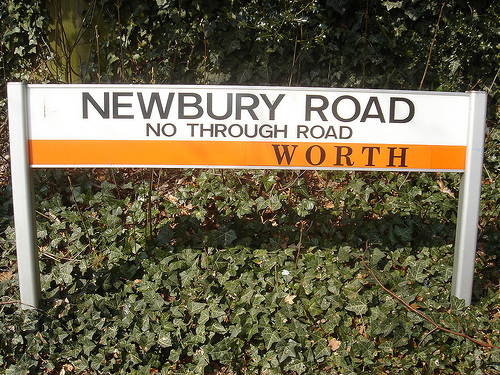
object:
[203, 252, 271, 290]
clovers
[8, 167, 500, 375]
ivy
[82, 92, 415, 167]
text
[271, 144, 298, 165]
letter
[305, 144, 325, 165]
letter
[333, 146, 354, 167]
letter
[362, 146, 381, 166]
letter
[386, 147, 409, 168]
letter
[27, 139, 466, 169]
orange area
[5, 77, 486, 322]
microphone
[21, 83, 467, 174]
sign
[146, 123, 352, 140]
letters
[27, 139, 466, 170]
backdrop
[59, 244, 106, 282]
leaves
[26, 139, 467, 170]
stripe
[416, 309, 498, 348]
twigs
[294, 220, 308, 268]
twigs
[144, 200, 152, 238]
twigs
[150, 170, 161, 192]
twigs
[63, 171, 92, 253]
twigs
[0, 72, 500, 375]
ground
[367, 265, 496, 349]
branch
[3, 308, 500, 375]
plant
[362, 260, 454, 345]
twigs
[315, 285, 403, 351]
greenery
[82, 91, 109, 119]
letters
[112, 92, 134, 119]
letters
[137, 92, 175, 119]
letters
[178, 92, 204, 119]
letters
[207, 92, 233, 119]
letters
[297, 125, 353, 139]
road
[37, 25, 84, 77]
sticks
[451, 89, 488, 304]
right pole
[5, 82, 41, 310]
stake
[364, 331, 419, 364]
leaves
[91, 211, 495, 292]
shadow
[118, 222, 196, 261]
greenery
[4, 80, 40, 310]
pole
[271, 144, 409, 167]
word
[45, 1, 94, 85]
tree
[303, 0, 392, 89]
tree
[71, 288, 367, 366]
vegetation